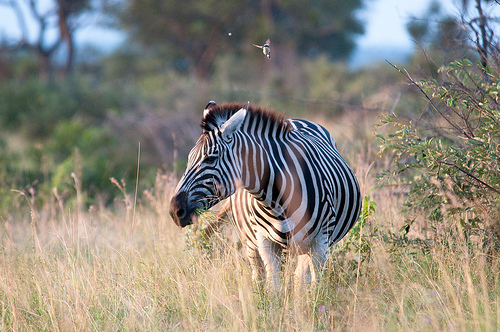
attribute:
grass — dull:
[38, 223, 158, 290]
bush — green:
[381, 56, 498, 233]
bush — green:
[363, 53, 499, 260]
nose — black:
[162, 172, 216, 241]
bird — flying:
[250, 36, 276, 60]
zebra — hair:
[167, 61, 410, 283]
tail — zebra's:
[187, 201, 234, 242]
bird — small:
[238, 25, 289, 80]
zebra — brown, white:
[153, 93, 370, 313]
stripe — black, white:
[238, 130, 248, 185]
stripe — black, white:
[185, 169, 220, 191]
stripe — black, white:
[229, 132, 244, 179]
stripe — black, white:
[210, 127, 219, 153]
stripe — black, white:
[323, 219, 337, 231]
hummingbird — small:
[250, 35, 275, 61]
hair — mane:
[198, 102, 292, 135]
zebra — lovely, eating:
[168, 98, 361, 304]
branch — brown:
[197, 197, 253, 261]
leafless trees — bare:
[1, 3, 91, 74]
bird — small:
[245, 35, 281, 65]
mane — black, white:
[209, 100, 290, 130]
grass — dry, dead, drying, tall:
[4, 110, 496, 325]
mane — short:
[200, 100, 287, 135]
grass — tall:
[0, 176, 499, 332]